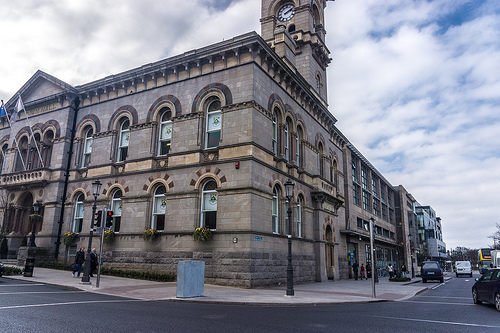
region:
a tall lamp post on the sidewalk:
[281, 176, 299, 298]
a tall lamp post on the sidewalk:
[20, 196, 55, 276]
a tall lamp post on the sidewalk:
[82, 175, 102, 284]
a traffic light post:
[91, 206, 113, 286]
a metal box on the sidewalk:
[174, 252, 205, 298]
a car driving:
[471, 267, 498, 310]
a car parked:
[419, 256, 442, 281]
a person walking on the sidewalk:
[71, 244, 83, 274]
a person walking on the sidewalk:
[87, 246, 97, 278]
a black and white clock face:
[277, 6, 293, 21]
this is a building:
[98, 75, 308, 172]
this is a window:
[205, 111, 220, 139]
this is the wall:
[231, 112, 251, 142]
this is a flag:
[12, 92, 25, 106]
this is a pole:
[368, 214, 379, 291]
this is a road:
[39, 291, 82, 328]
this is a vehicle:
[478, 267, 496, 303]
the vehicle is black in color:
[473, 282, 487, 294]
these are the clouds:
[403, 20, 481, 123]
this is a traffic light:
[91, 203, 113, 245]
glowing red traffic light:
[102, 207, 119, 221]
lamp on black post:
[277, 174, 303, 304]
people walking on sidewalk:
[64, 244, 107, 284]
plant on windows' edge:
[131, 224, 220, 244]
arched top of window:
[194, 83, 231, 133]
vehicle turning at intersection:
[461, 261, 498, 310]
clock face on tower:
[275, 4, 296, 26]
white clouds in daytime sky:
[384, 13, 453, 90]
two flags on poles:
[0, 79, 30, 151]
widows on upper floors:
[344, 158, 389, 220]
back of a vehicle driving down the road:
[451, 256, 474, 278]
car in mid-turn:
[463, 264, 498, 309]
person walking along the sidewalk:
[66, 239, 86, 278]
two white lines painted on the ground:
[3, 286, 117, 311]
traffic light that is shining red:
[84, 203, 114, 293]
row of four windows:
[73, 91, 246, 164]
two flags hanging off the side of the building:
[1, 95, 60, 170]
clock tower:
[252, 0, 345, 96]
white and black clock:
[276, 3, 299, 25]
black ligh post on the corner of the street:
[281, 176, 298, 303]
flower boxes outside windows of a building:
[185, 217, 226, 244]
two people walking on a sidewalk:
[69, 236, 107, 278]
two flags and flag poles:
[1, 80, 56, 178]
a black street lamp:
[278, 166, 298, 309]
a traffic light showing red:
[91, 197, 117, 290]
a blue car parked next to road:
[416, 257, 451, 295]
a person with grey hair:
[86, 241, 101, 263]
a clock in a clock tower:
[250, 2, 300, 22]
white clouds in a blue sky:
[378, 35, 485, 145]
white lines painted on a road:
[2, 287, 123, 331]